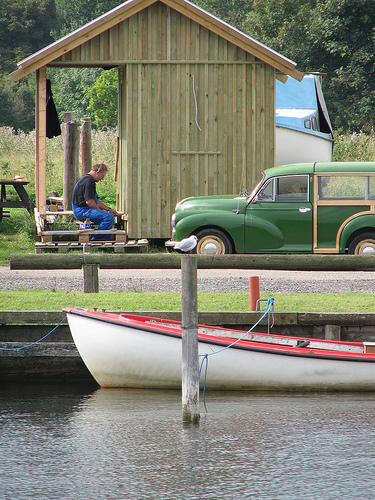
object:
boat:
[275, 74, 335, 193]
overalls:
[72, 174, 116, 241]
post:
[181, 255, 201, 422]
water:
[0, 365, 374, 500]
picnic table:
[0, 178, 36, 221]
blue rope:
[199, 297, 275, 414]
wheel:
[348, 232, 375, 271]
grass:
[147, 293, 156, 306]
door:
[244, 174, 313, 254]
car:
[164, 161, 375, 272]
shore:
[0, 285, 375, 372]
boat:
[61, 306, 375, 392]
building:
[8, 0, 305, 254]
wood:
[312, 171, 374, 254]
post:
[38, 64, 47, 212]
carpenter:
[71, 162, 120, 242]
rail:
[10, 254, 375, 271]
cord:
[192, 74, 202, 131]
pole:
[249, 275, 260, 311]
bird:
[164, 234, 199, 257]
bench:
[0, 179, 36, 227]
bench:
[34, 207, 127, 237]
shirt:
[73, 173, 96, 207]